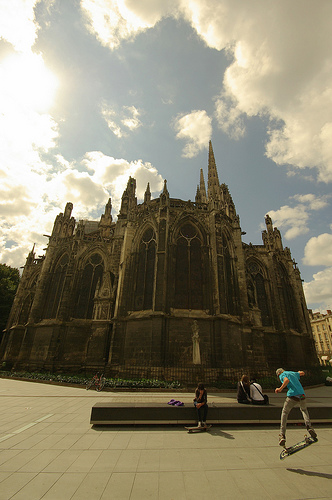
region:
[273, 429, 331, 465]
Skateboard in the middle of a trick.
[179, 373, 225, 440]
Person taking a break from skateboarding.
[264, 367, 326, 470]
Skateboarder performing a trick.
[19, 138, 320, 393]
Church with several spires and steeples.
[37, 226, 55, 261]
Protruding gargoyle statues to ward off evil spirits.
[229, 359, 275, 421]
Couple sitting and relaxing outside of the church.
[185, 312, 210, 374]
Representative statue in front of the church.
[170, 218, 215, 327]
Stained glass church windows.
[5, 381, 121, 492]
Flat stone sidewalk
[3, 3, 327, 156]
Partly cloudy sky.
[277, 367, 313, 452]
the boy is doing trick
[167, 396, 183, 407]
the sweater is purple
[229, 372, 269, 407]
the couple is sitting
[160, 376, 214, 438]
the sweater beside person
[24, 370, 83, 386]
greenery in front of gate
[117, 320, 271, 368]
the gate is black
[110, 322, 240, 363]
the gate is metal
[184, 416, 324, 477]
two skateboards are seen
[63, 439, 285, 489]
the pavement is gray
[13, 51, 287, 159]
the clouds are white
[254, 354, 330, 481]
In air on a skateboard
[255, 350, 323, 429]
Wearing bright blue shirt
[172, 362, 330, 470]
Doing tricks while friend looks on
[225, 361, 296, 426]
Two close friends looking the other way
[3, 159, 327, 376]
Gothic style structure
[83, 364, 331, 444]
Bench for relaxing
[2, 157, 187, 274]
Bright white clouds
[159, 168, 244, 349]
Dramatic stained glass windows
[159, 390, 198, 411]
Purple clothing on the bench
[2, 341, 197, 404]
Greenery in front of the structure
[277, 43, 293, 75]
part of dark cloud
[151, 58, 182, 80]
part of blue sky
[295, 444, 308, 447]
wheels of a skateboard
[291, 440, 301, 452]
section of a skateboard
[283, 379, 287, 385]
elbow of a skater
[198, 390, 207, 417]
a girl sitting on a bench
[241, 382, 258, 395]
two people on a bench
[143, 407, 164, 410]
section of a bench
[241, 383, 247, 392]
back of a woman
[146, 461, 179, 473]
section of a skating park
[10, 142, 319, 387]
an old cathedral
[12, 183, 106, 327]
damaged tower on a cathedral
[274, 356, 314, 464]
a skateboarder doing a jump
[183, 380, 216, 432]
a skateboarder sitting on a bench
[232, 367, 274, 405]
a couple sitting close on a bench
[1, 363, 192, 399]
a path of plants in front of a cathedral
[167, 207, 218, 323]
a huge cathedral window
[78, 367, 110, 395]
a bike leaning on a fence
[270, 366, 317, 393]
a blue shirt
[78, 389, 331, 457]
a bench in front of cathedral